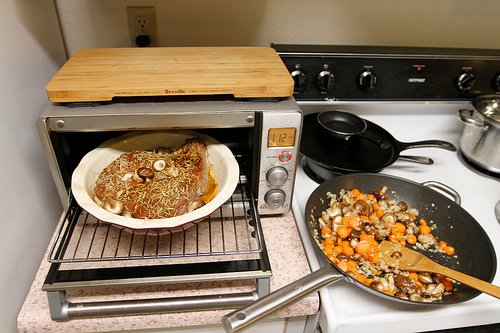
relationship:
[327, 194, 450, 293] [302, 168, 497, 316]
food in pan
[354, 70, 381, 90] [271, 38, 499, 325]
knob on stove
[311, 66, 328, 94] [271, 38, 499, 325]
knob on stove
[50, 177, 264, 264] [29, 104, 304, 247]
rack to microwave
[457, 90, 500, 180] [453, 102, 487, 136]
pot with handle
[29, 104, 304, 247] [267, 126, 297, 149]
toaster oven with display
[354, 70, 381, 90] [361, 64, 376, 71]
knob with writing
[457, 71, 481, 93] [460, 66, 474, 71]
knob with writing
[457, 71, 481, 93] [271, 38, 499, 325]
knob on stove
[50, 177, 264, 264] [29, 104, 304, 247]
rack of toaster oven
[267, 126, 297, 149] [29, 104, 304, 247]
interface of toaster oven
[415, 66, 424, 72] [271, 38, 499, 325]
light on range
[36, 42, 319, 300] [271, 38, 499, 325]
oven by stove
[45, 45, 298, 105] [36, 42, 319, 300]
board on oven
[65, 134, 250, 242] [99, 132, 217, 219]
bowl of food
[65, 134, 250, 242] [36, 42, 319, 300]
bowl in oven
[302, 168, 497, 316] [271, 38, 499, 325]
pan on stove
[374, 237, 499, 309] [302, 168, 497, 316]
spoon in pan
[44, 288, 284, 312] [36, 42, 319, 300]
handle of oven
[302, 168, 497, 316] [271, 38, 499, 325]
pan over stove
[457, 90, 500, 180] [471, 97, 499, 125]
pot with lid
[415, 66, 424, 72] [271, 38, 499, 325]
light on stove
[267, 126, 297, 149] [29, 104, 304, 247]
clock of toaster oven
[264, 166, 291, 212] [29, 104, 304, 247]
knobs of toaster oven